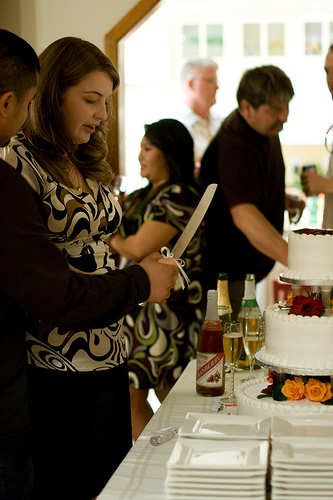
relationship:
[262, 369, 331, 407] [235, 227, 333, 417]
flowers on cake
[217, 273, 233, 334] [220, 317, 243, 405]
bottle in champagne glass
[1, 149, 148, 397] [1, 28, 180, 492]
shirt on man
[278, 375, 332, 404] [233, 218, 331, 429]
roses on cake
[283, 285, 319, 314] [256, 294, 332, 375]
floewr on cake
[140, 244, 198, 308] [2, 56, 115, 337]
hand on man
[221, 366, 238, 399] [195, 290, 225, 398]
handle on bottle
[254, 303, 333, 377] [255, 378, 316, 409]
cake with flower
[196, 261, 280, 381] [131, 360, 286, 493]
bottles on table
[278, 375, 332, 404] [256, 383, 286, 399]
roses with leaves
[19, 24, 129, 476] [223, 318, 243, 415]
woman looking at drink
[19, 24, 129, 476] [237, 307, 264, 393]
woman looking at drink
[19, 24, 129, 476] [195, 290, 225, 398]
woman looking at bottle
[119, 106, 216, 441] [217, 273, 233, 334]
woman looking at bottle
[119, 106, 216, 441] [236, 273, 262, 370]
woman looking at bottles